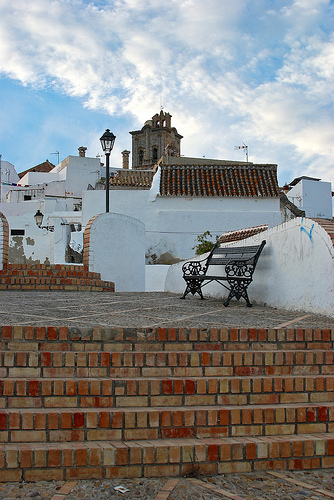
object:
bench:
[180, 239, 267, 309]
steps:
[1, 463, 38, 484]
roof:
[148, 161, 283, 202]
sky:
[0, 0, 334, 192]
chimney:
[121, 148, 131, 168]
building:
[145, 153, 306, 257]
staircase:
[0, 290, 334, 484]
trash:
[113, 482, 131, 494]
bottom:
[0, 455, 334, 499]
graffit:
[297, 220, 334, 266]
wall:
[165, 212, 334, 318]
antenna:
[234, 141, 248, 162]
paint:
[144, 218, 223, 265]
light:
[98, 127, 116, 156]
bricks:
[85, 407, 98, 430]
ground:
[0, 468, 334, 500]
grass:
[180, 448, 206, 481]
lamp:
[98, 127, 117, 214]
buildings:
[128, 105, 184, 169]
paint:
[265, 220, 313, 263]